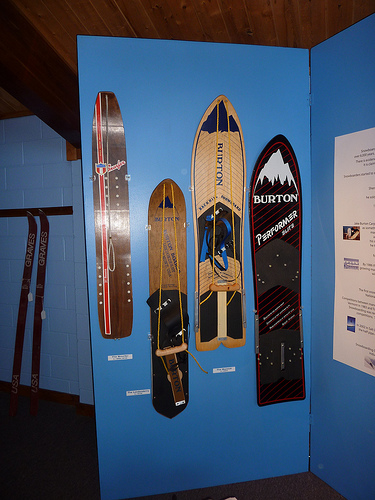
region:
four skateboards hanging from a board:
[83, 82, 316, 432]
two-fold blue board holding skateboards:
[61, 13, 373, 498]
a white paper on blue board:
[324, 120, 373, 391]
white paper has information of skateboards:
[81, 82, 373, 430]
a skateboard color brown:
[85, 87, 141, 351]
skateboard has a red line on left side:
[88, 86, 142, 354]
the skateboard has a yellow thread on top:
[137, 176, 194, 427]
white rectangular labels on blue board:
[95, 345, 238, 414]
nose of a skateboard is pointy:
[185, 82, 252, 172]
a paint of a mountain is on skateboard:
[252, 124, 306, 210]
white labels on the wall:
[206, 361, 248, 384]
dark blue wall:
[159, 422, 257, 480]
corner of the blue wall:
[263, 419, 336, 466]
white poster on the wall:
[331, 114, 370, 403]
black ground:
[28, 427, 83, 476]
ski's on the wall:
[4, 211, 64, 399]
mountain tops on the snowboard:
[248, 134, 310, 214]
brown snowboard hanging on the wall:
[177, 96, 260, 347]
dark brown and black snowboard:
[131, 178, 195, 440]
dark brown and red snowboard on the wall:
[80, 86, 140, 337]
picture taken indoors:
[74, 165, 330, 384]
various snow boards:
[95, 221, 308, 382]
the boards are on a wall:
[114, 192, 347, 322]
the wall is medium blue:
[95, 215, 331, 415]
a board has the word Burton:
[253, 150, 331, 245]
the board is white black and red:
[241, 149, 308, 467]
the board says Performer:
[249, 156, 363, 366]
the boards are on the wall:
[93, 200, 350, 418]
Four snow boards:
[92, 187, 360, 388]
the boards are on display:
[84, 163, 334, 426]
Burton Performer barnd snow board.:
[248, 126, 310, 406]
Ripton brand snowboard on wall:
[190, 92, 250, 353]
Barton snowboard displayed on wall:
[143, 173, 194, 419]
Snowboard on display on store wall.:
[90, 87, 142, 346]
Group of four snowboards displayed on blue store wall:
[86, 90, 306, 415]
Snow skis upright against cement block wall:
[4, 199, 59, 396]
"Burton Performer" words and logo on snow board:
[246, 135, 301, 242]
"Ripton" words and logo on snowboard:
[186, 91, 243, 211]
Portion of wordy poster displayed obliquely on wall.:
[322, 112, 369, 377]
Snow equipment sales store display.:
[8, 91, 309, 420]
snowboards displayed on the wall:
[57, 52, 315, 415]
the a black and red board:
[247, 129, 311, 418]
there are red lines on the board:
[243, 143, 314, 251]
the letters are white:
[244, 184, 303, 209]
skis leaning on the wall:
[4, 199, 66, 402]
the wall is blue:
[5, 135, 78, 394]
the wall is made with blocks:
[2, 134, 66, 205]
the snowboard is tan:
[189, 84, 252, 349]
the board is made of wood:
[194, 123, 244, 351]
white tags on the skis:
[9, 280, 51, 320]